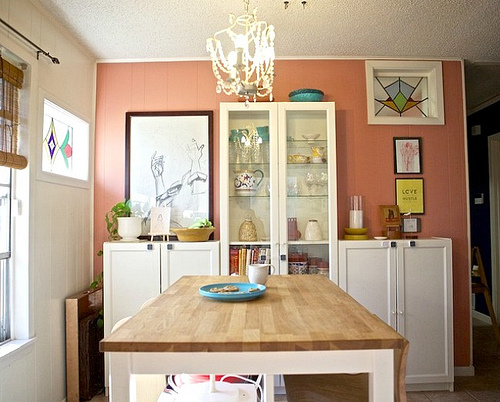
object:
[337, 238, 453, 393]
cabinet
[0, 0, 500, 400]
dining room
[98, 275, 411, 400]
table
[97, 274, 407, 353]
butcher block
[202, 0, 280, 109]
chandelier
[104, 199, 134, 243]
plant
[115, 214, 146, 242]
vase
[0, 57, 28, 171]
blinds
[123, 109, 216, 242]
picture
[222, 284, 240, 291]
cookies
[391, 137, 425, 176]
print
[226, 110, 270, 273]
glass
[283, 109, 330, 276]
windows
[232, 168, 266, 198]
items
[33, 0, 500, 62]
ceiling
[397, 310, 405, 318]
knob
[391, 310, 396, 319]
knob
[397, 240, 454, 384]
cabinet door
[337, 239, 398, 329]
cabinet door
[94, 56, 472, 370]
room peach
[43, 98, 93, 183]
window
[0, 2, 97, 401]
wall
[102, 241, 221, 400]
cabinet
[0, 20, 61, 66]
rod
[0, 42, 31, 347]
window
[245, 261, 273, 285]
cup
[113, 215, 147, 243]
pot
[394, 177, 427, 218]
picture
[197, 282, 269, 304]
plate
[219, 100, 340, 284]
cabinet